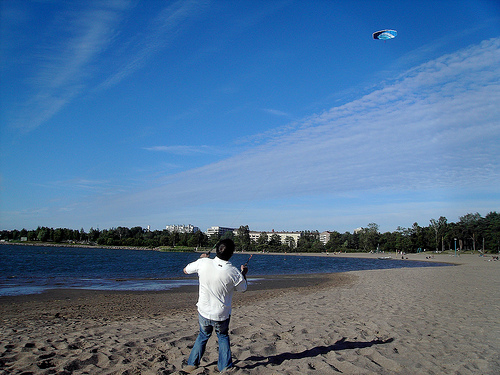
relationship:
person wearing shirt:
[183, 237, 252, 375] [184, 255, 248, 323]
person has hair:
[183, 237, 252, 375] [215, 238, 235, 264]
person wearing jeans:
[183, 237, 252, 375] [186, 310, 235, 369]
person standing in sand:
[183, 237, 252, 375] [0, 251, 499, 374]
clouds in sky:
[131, 38, 500, 206] [0, 1, 500, 236]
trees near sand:
[0, 209, 500, 255] [0, 251, 499, 374]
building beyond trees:
[200, 224, 325, 255] [0, 209, 500, 255]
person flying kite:
[183, 237, 252, 375] [372, 26, 398, 45]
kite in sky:
[372, 26, 398, 45] [0, 1, 500, 236]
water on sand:
[1, 241, 457, 288] [0, 251, 499, 374]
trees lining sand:
[0, 209, 500, 255] [0, 251, 499, 374]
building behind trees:
[200, 224, 325, 255] [0, 209, 500, 255]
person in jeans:
[183, 237, 252, 375] [186, 310, 235, 369]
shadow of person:
[202, 334, 398, 373] [183, 237, 252, 375]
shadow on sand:
[202, 334, 398, 373] [0, 251, 499, 374]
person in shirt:
[183, 237, 252, 375] [184, 255, 248, 323]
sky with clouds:
[0, 1, 500, 236] [131, 38, 500, 206]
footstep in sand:
[160, 345, 185, 361] [0, 251, 499, 374]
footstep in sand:
[125, 340, 143, 350] [0, 251, 499, 374]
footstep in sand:
[147, 342, 163, 350] [0, 251, 499, 374]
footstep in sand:
[34, 357, 59, 371] [0, 251, 499, 374]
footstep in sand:
[67, 342, 85, 353] [0, 251, 499, 374]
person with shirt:
[183, 237, 252, 375] [184, 255, 248, 323]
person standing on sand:
[183, 237, 252, 375] [0, 251, 499, 374]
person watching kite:
[183, 237, 252, 375] [372, 26, 398, 45]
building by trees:
[200, 224, 325, 255] [0, 209, 500, 255]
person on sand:
[183, 237, 252, 375] [0, 251, 499, 374]